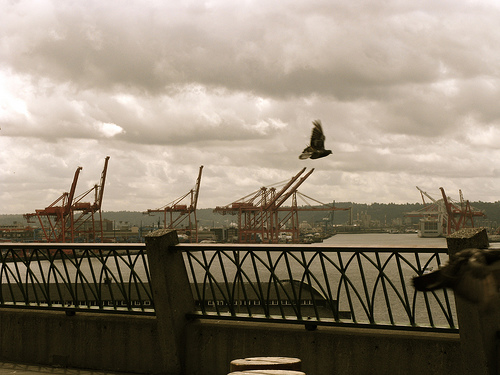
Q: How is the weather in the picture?
A: It is cloudy.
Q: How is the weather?
A: It is cloudy.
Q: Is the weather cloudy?
A: Yes, it is cloudy.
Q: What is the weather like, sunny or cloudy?
A: It is cloudy.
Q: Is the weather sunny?
A: No, it is cloudy.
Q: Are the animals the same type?
A: No, they are birds and dogs.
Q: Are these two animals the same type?
A: No, they are birds and dogs.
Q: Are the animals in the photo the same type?
A: No, they are birds and dogs.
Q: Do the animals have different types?
A: Yes, they are birds and dogs.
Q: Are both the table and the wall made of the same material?
A: No, the table is made of plastic and the wall is made of cement.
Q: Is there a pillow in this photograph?
A: No, there are no pillows.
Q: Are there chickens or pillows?
A: No, there are no pillows or chickens.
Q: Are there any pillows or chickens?
A: No, there are no pillows or chickens.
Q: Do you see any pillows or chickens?
A: No, there are no pillows or chickens.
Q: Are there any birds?
A: Yes, there is a bird.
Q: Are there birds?
A: Yes, there is a bird.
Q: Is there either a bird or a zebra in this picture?
A: Yes, there is a bird.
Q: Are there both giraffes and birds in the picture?
A: No, there is a bird but no giraffes.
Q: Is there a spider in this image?
A: No, there are no spiders.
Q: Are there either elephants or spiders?
A: No, there are no spiders or elephants.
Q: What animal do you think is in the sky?
A: The bird is in the sky.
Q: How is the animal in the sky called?
A: The animal is a bird.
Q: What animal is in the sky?
A: The animal is a bird.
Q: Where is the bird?
A: The bird is in the sky.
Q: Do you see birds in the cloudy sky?
A: Yes, there is a bird in the sky.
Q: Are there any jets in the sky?
A: No, there is a bird in the sky.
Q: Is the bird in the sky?
A: Yes, the bird is in the sky.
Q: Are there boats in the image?
A: Yes, there is a boat.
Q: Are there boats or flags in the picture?
A: Yes, there is a boat.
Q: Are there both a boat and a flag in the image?
A: No, there is a boat but no flags.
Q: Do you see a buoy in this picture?
A: No, there are no buoys.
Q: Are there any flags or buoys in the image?
A: No, there are no buoys or flags.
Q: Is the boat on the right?
A: Yes, the boat is on the right of the image.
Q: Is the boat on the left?
A: No, the boat is on the right of the image.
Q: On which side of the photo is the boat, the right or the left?
A: The boat is on the right of the image.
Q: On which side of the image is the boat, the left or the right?
A: The boat is on the right of the image.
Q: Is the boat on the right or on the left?
A: The boat is on the right of the image.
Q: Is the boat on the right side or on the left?
A: The boat is on the right of the image.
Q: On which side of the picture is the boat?
A: The boat is on the right of the image.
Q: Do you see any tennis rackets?
A: No, there are no tennis rackets.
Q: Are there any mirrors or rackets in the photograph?
A: No, there are no rackets or mirrors.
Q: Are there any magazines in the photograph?
A: No, there are no magazines.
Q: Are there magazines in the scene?
A: No, there are no magazines.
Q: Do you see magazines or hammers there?
A: No, there are no magazines or hammers.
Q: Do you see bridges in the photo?
A: Yes, there is a bridge.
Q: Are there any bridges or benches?
A: Yes, there is a bridge.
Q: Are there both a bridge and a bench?
A: No, there is a bridge but no benches.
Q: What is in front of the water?
A: The bridge is in front of the water.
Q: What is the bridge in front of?
A: The bridge is in front of the water.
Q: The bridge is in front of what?
A: The bridge is in front of the water.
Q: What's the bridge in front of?
A: The bridge is in front of the water.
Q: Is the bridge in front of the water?
A: Yes, the bridge is in front of the water.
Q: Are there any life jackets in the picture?
A: No, there are no life jackets.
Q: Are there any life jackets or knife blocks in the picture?
A: No, there are no life jackets or knife blocks.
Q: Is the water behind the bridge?
A: Yes, the water is behind the bridge.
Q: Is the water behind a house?
A: No, the water is behind the bridge.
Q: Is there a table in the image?
A: Yes, there is a table.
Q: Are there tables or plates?
A: Yes, there is a table.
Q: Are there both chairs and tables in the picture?
A: No, there is a table but no chairs.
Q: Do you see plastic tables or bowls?
A: Yes, there is a plastic table.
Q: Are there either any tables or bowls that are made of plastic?
A: Yes, the table is made of plastic.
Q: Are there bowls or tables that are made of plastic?
A: Yes, the table is made of plastic.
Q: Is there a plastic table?
A: Yes, there is a table that is made of plastic.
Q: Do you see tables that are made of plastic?
A: Yes, there is a table that is made of plastic.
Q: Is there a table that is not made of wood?
A: Yes, there is a table that is made of plastic.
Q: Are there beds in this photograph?
A: No, there are no beds.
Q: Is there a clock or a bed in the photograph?
A: No, there are no beds or clocks.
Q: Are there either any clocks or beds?
A: No, there are no beds or clocks.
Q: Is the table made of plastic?
A: Yes, the table is made of plastic.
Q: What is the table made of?
A: The table is made of plastic.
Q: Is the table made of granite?
A: No, the table is made of plastic.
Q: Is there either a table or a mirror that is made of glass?
A: No, there is a table but it is made of plastic.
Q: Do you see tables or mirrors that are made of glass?
A: No, there is a table but it is made of plastic.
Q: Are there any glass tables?
A: No, there is a table but it is made of plastic.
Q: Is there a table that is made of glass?
A: No, there is a table but it is made of plastic.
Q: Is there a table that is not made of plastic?
A: No, there is a table but it is made of plastic.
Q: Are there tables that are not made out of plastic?
A: No, there is a table but it is made of plastic.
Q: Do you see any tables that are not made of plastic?
A: No, there is a table but it is made of plastic.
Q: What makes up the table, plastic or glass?
A: The table is made of plastic.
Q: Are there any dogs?
A: Yes, there is a dog.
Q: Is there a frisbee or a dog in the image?
A: Yes, there is a dog.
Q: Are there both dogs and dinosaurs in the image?
A: No, there is a dog but no dinosaurs.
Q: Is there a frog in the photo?
A: No, there are no frogs.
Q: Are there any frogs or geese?
A: No, there are no frogs or geese.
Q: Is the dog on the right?
A: Yes, the dog is on the right of the image.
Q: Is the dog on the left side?
A: No, the dog is on the right of the image.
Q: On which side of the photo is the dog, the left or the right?
A: The dog is on the right of the image.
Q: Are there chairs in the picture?
A: No, there are no chairs.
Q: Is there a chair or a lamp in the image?
A: No, there are no chairs or lamps.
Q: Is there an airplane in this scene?
A: No, there are no airplanes.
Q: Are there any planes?
A: No, there are no planes.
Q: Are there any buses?
A: No, there are no buses.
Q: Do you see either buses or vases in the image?
A: No, there are no buses or vases.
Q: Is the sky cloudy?
A: Yes, the sky is cloudy.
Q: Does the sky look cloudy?
A: Yes, the sky is cloudy.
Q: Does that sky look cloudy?
A: Yes, the sky is cloudy.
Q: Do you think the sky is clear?
A: No, the sky is cloudy.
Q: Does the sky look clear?
A: No, the sky is cloudy.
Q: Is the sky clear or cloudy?
A: The sky is cloudy.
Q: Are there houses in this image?
A: No, there are no houses.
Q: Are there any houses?
A: No, there are no houses.